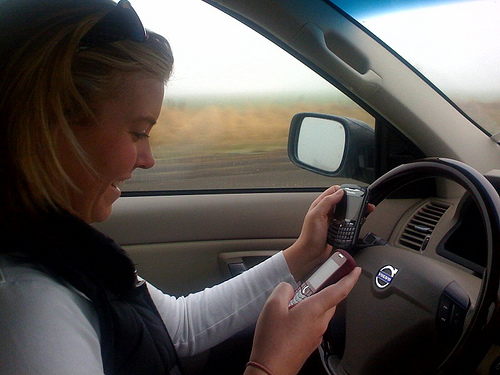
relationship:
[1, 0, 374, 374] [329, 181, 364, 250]
girl holding cell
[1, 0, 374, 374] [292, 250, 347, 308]
girl holding cell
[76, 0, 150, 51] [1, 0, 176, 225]
sunglasses on head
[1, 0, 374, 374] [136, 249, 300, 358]
girl wearing long sleeve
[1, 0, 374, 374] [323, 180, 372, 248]
girl has phones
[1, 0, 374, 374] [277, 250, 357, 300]
girl has phones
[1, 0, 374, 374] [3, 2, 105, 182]
girl has hair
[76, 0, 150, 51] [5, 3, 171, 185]
sunglasses in hair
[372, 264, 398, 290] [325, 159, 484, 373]
logo on steering wheel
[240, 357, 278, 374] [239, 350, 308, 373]
tie on wrist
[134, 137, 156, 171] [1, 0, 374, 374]
nose of girl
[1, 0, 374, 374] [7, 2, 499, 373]
girl sitting in car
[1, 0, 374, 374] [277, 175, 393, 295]
girl holding phones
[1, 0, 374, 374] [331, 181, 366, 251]
girl holding cellphone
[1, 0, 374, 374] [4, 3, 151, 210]
girl with hair